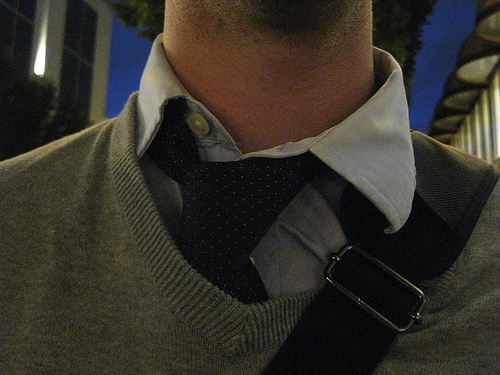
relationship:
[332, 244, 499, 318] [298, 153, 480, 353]
attachment for adjusting strap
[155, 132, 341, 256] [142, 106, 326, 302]
knot in top of neck tie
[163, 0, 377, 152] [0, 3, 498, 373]
neck of male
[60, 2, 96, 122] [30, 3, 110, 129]
window with frame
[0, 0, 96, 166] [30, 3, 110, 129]
window with frame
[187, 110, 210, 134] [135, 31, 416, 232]
button on collar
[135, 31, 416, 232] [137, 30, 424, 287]
collar of shirt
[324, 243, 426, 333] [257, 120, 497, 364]
buckle on strap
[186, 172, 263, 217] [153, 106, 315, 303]
pattern on neck tie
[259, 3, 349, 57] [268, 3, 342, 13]
stubble on chin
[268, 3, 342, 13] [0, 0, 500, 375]
chin of male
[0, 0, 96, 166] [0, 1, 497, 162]
window on side of building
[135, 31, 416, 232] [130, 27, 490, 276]
collar of shirt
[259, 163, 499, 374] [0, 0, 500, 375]
strap on front of male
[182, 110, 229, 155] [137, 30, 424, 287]
button on shirt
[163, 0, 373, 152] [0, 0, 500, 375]
neck on male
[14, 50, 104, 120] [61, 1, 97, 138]
four panel window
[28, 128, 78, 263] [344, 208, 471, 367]
shoulder pad on strap of bag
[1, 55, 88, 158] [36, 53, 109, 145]
bush in background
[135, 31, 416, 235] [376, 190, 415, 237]
collar on end of collar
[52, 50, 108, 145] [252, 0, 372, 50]
five oclock shadow